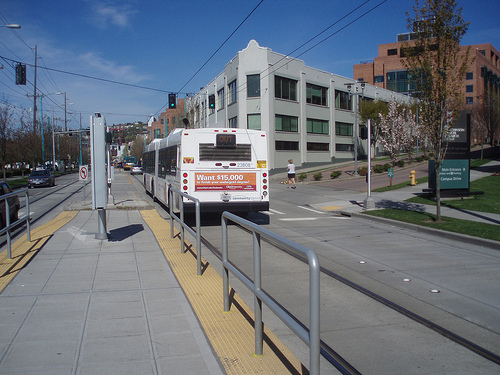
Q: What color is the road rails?
A: Grey.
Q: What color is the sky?
A: Blue and white.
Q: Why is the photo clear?
A: Its during the day.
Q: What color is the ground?
A: Grey.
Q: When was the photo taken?
A: Daytime.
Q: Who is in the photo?
A: A person.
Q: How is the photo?
A: Clear.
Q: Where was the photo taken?
A: Behind bus.